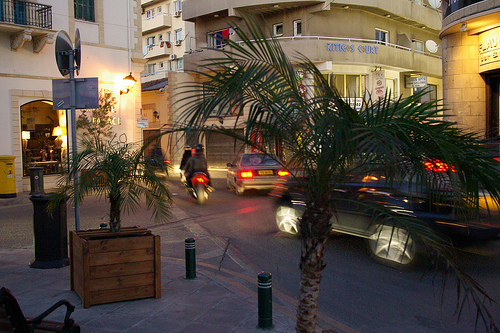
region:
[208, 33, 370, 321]
palm tree on the side of the road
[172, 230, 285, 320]
two poles on the curve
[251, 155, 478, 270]
black car behind the palm tree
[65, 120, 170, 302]
wooden box with plant in it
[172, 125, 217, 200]
motorcycle going down the road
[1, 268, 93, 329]
bench on the side walk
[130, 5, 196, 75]
balcony on the yellow building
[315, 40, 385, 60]
blue letters on the building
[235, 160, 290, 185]
tail lights on the car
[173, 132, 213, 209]
man on motorcycle with a helmet on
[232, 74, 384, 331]
A small palm tree on the sidewalk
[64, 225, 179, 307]
A large wooden crate on the sidewalk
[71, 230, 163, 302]
The crate is made of wooden planks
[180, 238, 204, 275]
Short, green poles by the road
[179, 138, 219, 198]
A man riding a motorcycle in the street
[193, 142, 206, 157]
A blue helmet on the man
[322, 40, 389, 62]
Blue writing on the stone building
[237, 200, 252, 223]
Reflection of a red light on the road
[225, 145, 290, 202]
A small grey car driving on the road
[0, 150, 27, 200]
A yellow trash can by the building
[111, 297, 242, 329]
The floor is made of concrete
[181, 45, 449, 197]
The leaves are long and green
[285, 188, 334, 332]
The tree trunk is gray and brown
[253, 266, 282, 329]
The pole is the color green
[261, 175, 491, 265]
A car is passing by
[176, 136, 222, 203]
A person on the motorcycle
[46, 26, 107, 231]
The sign on the corner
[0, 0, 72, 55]
A balcony on the side of the building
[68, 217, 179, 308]
A wooden box on the corner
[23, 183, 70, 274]
A trash can on the corner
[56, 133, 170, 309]
A small tree in a wood planter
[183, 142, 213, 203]
people riding a motorcycle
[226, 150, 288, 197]
The back of a brown car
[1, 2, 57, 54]
A balcony with black railing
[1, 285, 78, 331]
End of a bench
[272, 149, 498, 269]
A black car driving on the road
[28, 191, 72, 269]
An outdoor garbage can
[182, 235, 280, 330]
Concrete poles sticking out of the ground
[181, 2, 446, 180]
A building with blue lettering on it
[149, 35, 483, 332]
A small palm tree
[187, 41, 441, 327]
the small palm tree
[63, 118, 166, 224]
the smaller palm tree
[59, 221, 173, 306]
the box under the palm tree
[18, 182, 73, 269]
the waste bin on the sidewalk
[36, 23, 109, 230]
the signs on the pole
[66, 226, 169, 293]
the box is wooden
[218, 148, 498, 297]
two cars in the street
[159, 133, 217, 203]
the motorcycle in the street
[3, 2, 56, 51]
the small balcony on the building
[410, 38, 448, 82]
the satellite dish on the building